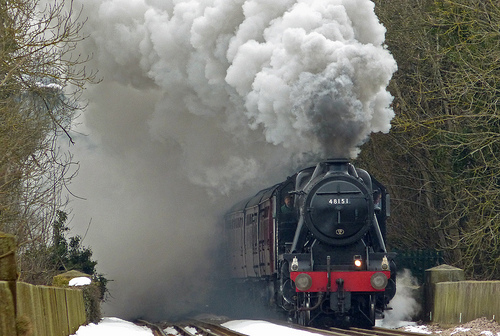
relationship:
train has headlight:
[200, 145, 391, 335] [293, 269, 390, 296]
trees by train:
[390, 11, 500, 174] [200, 145, 391, 335]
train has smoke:
[200, 145, 391, 335] [62, 10, 389, 315]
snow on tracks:
[88, 311, 268, 336] [144, 298, 423, 334]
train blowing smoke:
[200, 145, 391, 335] [62, 10, 389, 315]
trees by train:
[432, 4, 500, 281] [200, 145, 391, 335]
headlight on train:
[293, 269, 390, 296] [200, 145, 391, 335]